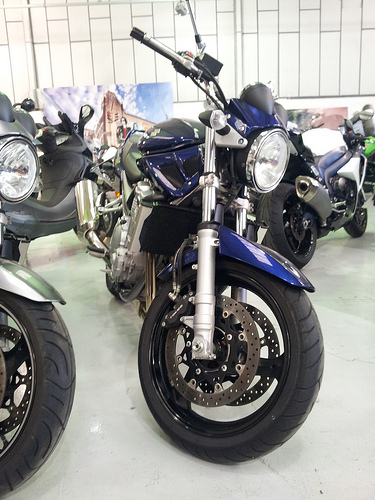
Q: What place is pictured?
A: It is a garage.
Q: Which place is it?
A: It is a garage.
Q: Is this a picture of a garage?
A: Yes, it is showing a garage.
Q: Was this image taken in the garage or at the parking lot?
A: It was taken at the garage.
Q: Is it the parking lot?
A: No, it is the garage.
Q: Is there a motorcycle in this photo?
A: Yes, there is a motorcycle.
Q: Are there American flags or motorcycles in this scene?
A: Yes, there is a motorcycle.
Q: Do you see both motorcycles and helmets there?
A: No, there is a motorcycle but no helmets.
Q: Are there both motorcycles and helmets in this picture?
A: No, there is a motorcycle but no helmets.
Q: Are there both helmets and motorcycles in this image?
A: No, there is a motorcycle but no helmets.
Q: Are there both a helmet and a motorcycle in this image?
A: No, there is a motorcycle but no helmets.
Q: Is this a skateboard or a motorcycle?
A: This is a motorcycle.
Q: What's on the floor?
A: The motorcycle is on the floor.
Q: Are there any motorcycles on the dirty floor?
A: Yes, there is a motorcycle on the floor.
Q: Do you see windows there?
A: Yes, there is a window.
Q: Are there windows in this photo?
A: Yes, there is a window.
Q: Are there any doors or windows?
A: Yes, there is a window.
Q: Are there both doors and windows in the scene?
A: No, there is a window but no doors.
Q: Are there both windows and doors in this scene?
A: No, there is a window but no doors.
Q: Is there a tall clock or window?
A: Yes, there is a tall window.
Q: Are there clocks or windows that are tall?
A: Yes, the window is tall.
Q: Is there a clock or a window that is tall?
A: Yes, the window is tall.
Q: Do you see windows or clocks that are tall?
A: Yes, the window is tall.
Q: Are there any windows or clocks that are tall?
A: Yes, the window is tall.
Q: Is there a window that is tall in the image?
A: Yes, there is a tall window.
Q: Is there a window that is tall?
A: Yes, there is a window that is tall.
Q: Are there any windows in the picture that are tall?
A: Yes, there is a window that is tall.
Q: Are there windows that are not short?
A: Yes, there is a tall window.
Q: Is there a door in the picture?
A: No, there are no doors.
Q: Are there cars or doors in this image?
A: No, there are no doors or cars.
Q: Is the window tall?
A: Yes, the window is tall.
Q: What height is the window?
A: The window is tall.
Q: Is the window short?
A: No, the window is tall.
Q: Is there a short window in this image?
A: No, there is a window but it is tall.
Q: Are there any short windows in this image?
A: No, there is a window but it is tall.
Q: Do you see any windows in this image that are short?
A: No, there is a window but it is tall.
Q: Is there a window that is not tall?
A: No, there is a window but it is tall.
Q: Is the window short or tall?
A: The window is tall.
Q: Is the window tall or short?
A: The window is tall.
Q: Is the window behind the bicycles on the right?
A: Yes, the window is behind the bikes.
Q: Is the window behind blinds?
A: No, the window is behind the bikes.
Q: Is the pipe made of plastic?
A: No, the pipe is made of chrome.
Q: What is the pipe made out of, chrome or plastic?
A: The pipe is made of chrome.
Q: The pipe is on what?
A: The pipe is on the motorbike.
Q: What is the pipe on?
A: The pipe is on the motorbike.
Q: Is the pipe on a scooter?
A: No, the pipe is on the motorcycle.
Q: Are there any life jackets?
A: No, there are no life jackets.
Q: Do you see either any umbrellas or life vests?
A: No, there are no life vests or umbrellas.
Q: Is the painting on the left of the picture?
A: Yes, the painting is on the left of the image.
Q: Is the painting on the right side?
A: No, the painting is on the left of the image.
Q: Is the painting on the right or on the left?
A: The painting is on the left of the image.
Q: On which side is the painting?
A: The painting is on the left of the image.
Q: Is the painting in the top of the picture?
A: Yes, the painting is in the top of the image.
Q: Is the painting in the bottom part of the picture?
A: No, the painting is in the top of the image.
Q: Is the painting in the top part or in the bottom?
A: The painting is in the top of the image.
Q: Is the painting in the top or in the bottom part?
A: The painting is in the top of the image.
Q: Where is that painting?
A: The painting is in the garage.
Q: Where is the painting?
A: The painting is in the garage.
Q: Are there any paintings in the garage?
A: Yes, there is a painting in the garage.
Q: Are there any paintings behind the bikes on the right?
A: Yes, there is a painting behind the bicycles.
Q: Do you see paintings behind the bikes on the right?
A: Yes, there is a painting behind the bicycles.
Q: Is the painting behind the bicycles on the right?
A: Yes, the painting is behind the bicycles.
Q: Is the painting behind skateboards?
A: No, the painting is behind the bicycles.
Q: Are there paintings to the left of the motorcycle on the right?
A: Yes, there is a painting to the left of the motorcycle.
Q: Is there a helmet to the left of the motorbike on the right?
A: No, there is a painting to the left of the motorbike.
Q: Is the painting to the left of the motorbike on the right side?
A: Yes, the painting is to the left of the motorbike.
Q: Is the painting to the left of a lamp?
A: No, the painting is to the left of the motorbike.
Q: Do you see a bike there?
A: Yes, there are bikes.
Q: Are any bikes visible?
A: Yes, there are bikes.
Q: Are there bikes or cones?
A: Yes, there are bikes.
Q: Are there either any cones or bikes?
A: Yes, there are bikes.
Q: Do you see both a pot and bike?
A: No, there are bikes but no pots.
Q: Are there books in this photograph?
A: No, there are no books.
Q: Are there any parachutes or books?
A: No, there are no books or parachutes.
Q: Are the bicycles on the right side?
A: Yes, the bicycles are on the right of the image.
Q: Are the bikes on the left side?
A: No, the bikes are on the right of the image.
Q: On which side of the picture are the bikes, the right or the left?
A: The bikes are on the right of the image.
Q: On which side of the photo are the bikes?
A: The bikes are on the right of the image.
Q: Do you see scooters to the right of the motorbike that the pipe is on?
A: No, there are bikes to the right of the motorbike.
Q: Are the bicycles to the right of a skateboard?
A: No, the bicycles are to the right of the motorbike.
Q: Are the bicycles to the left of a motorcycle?
A: No, the bicycles are to the right of a motorcycle.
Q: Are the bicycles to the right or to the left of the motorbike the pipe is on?
A: The bicycles are to the right of the motorbike.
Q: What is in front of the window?
A: The bicycles are in front of the window.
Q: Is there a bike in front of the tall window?
A: Yes, there are bikes in front of the window.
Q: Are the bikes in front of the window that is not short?
A: Yes, the bikes are in front of the window.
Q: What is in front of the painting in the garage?
A: The bicycles are in front of the painting.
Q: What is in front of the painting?
A: The bicycles are in front of the painting.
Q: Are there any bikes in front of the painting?
A: Yes, there are bikes in front of the painting.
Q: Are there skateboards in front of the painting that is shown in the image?
A: No, there are bikes in front of the painting.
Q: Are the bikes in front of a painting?
A: Yes, the bikes are in front of a painting.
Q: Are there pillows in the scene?
A: No, there are no pillows.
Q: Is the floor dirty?
A: Yes, the floor is dirty.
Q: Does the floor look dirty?
A: Yes, the floor is dirty.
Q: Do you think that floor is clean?
A: No, the floor is dirty.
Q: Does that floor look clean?
A: No, the floor is dirty.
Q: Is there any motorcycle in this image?
A: Yes, there is a motorcycle.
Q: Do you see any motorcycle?
A: Yes, there is a motorcycle.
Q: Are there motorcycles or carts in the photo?
A: Yes, there is a motorcycle.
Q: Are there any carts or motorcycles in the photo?
A: Yes, there is a motorcycle.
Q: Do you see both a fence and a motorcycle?
A: No, there is a motorcycle but no fences.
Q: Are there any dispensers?
A: No, there are no dispensers.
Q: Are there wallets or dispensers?
A: No, there are no dispensers or wallets.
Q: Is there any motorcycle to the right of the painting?
A: Yes, there is a motorcycle to the right of the painting.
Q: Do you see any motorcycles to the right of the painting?
A: Yes, there is a motorcycle to the right of the painting.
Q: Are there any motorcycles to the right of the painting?
A: Yes, there is a motorcycle to the right of the painting.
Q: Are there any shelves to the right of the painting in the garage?
A: No, there is a motorcycle to the right of the painting.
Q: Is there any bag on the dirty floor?
A: No, there is a motorcycle on the floor.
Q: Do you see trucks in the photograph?
A: No, there are no trucks.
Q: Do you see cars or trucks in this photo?
A: No, there are no trucks or cars.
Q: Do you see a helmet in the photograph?
A: No, there are no helmets.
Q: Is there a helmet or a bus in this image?
A: No, there are no helmets or buses.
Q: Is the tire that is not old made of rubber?
A: Yes, the tire is made of rubber.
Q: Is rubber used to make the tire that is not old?
A: Yes, the tire is made of rubber.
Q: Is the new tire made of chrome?
A: No, the tire is made of rubber.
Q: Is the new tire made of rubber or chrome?
A: The tire is made of rubber.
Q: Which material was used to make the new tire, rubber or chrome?
A: The tire is made of rubber.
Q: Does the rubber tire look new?
A: Yes, the tire is new.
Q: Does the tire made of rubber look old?
A: No, the tire is new.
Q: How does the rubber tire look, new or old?
A: The tire is new.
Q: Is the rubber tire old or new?
A: The tire is new.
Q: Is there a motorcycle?
A: Yes, there is a motorcycle.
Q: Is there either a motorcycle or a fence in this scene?
A: Yes, there is a motorcycle.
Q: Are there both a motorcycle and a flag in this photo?
A: No, there is a motorcycle but no flags.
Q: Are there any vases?
A: No, there are no vases.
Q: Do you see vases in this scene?
A: No, there are no vases.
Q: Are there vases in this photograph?
A: No, there are no vases.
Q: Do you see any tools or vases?
A: No, there are no vases or tools.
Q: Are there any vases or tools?
A: No, there are no vases or tools.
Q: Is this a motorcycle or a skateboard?
A: This is a motorcycle.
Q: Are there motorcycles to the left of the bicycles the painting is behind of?
A: Yes, there is a motorcycle to the left of the bicycles.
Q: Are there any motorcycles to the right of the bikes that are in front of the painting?
A: No, the motorcycle is to the left of the bikes.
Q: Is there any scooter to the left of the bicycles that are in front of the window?
A: No, there is a motorcycle to the left of the bikes.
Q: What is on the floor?
A: The motorbike is on the floor.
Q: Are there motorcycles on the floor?
A: Yes, there is a motorcycle on the floor.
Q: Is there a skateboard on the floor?
A: No, there is a motorcycle on the floor.